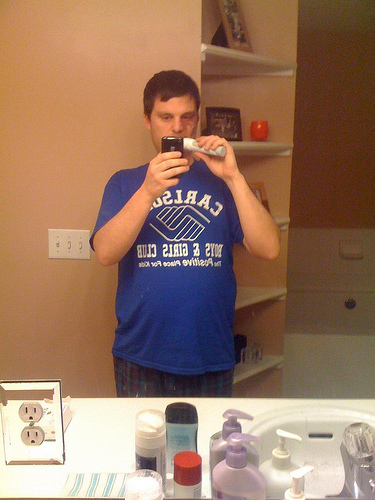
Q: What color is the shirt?
A: Blue.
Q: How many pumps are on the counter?
A: Four.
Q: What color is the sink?
A: White.